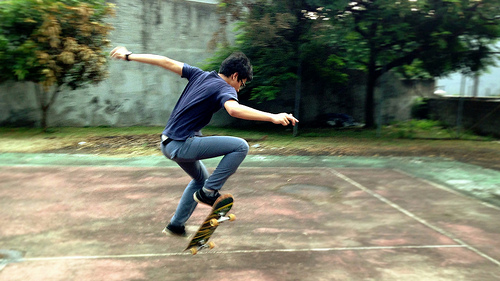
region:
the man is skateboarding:
[70, 15, 288, 267]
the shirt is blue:
[155, 63, 245, 176]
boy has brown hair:
[168, 50, 248, 82]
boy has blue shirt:
[168, 78, 220, 145]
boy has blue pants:
[165, 144, 240, 225]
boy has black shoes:
[158, 173, 230, 267]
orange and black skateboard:
[190, 188, 247, 250]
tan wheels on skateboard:
[197, 211, 234, 255]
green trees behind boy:
[202, 30, 442, 147]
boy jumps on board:
[165, 153, 343, 274]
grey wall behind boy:
[84, 0, 161, 110]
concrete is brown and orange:
[220, 174, 328, 279]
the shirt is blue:
[175, 63, 227, 146]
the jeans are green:
[158, 141, 258, 193]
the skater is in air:
[110, 40, 292, 247]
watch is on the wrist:
[113, 43, 138, 68]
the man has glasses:
[113, 45, 280, 225]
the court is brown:
[311, 192, 403, 265]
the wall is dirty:
[135, 15, 225, 42]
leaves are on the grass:
[290, 137, 431, 149]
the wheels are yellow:
[188, 201, 250, 261]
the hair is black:
[217, 54, 253, 76]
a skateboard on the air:
[184, 194, 239, 258]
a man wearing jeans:
[140, 132, 249, 228]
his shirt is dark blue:
[163, 52, 238, 144]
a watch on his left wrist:
[122, 48, 132, 65]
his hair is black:
[209, 49, 256, 79]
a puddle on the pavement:
[277, 176, 334, 209]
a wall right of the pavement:
[412, 87, 498, 142]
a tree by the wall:
[5, 0, 102, 140]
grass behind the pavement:
[8, 100, 465, 158]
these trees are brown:
[36, 0, 119, 112]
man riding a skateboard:
[102, 52, 307, 252]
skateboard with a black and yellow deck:
[179, 194, 241, 261]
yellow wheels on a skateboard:
[185, 209, 237, 260]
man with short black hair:
[217, 50, 257, 100]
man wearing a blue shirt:
[97, 38, 297, 235]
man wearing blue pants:
[104, 50, 314, 232]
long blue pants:
[150, 124, 246, 240]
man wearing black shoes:
[95, 28, 283, 246]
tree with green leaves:
[304, 3, 491, 154]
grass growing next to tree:
[330, 112, 497, 152]